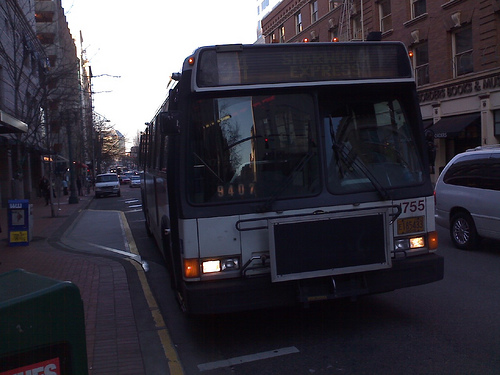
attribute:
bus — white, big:
[137, 44, 443, 307]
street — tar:
[119, 171, 499, 374]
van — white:
[95, 174, 120, 196]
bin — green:
[6, 276, 87, 374]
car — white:
[126, 176, 138, 186]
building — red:
[260, 3, 500, 93]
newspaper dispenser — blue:
[9, 200, 34, 243]